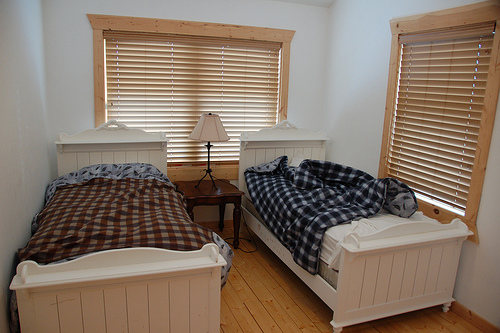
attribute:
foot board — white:
[328, 218, 473, 331]